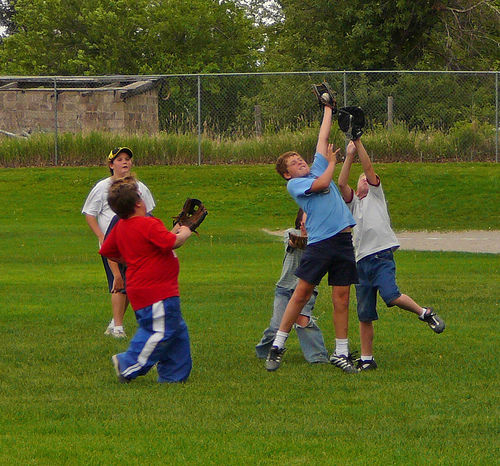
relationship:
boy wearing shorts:
[263, 105, 359, 374] [294, 232, 357, 286]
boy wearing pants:
[93, 170, 200, 387] [106, 291, 196, 385]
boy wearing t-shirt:
[93, 170, 200, 387] [91, 211, 183, 312]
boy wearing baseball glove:
[98, 175, 208, 385] [173, 194, 214, 233]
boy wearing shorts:
[98, 175, 208, 385] [274, 222, 361, 292]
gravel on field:
[402, 229, 498, 254] [2, 165, 481, 464]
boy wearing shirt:
[338, 135, 446, 375] [342, 171, 398, 258]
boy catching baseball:
[270, 147, 349, 365] [287, 78, 432, 156]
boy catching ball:
[98, 175, 208, 385] [321, 92, 330, 102]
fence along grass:
[0, 67, 498, 166] [3, 130, 498, 464]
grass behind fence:
[181, 131, 274, 155] [61, 81, 185, 150]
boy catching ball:
[263, 105, 359, 374] [315, 80, 332, 102]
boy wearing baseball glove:
[98, 175, 208, 385] [171, 196, 207, 233]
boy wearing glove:
[338, 135, 446, 375] [332, 101, 370, 140]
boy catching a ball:
[263, 105, 359, 374] [307, 82, 342, 113]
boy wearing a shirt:
[269, 106, 363, 380] [265, 148, 352, 255]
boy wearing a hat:
[77, 137, 159, 342] [78, 129, 143, 163]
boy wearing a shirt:
[324, 147, 468, 377] [327, 183, 413, 257]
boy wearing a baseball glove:
[98, 175, 208, 385] [171, 197, 209, 239]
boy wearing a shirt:
[98, 175, 208, 385] [70, 207, 191, 317]